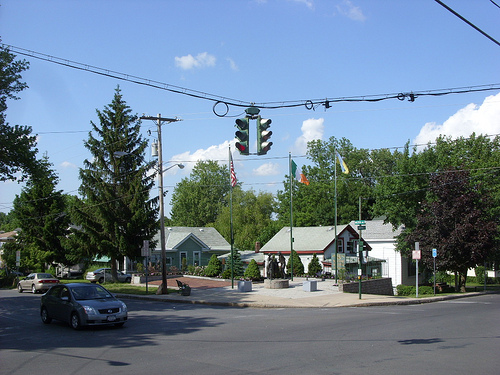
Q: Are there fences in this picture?
A: No, there are no fences.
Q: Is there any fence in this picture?
A: No, there are no fences.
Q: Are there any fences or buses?
A: No, there are no fences or buses.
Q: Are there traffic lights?
A: Yes, there is a traffic light.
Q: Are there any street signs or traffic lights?
A: Yes, there is a traffic light.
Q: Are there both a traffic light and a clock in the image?
A: No, there is a traffic light but no clocks.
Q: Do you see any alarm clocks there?
A: No, there are no alarm clocks.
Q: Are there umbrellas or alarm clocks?
A: No, there are no alarm clocks or umbrellas.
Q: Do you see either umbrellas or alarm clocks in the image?
A: No, there are no alarm clocks or umbrellas.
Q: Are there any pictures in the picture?
A: No, there are no pictures.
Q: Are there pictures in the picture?
A: No, there are no pictures.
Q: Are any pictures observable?
A: No, there are no pictures.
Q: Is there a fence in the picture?
A: No, there are no fences.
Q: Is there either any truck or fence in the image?
A: No, there are no fences or trucks.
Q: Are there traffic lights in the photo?
A: Yes, there is a traffic light.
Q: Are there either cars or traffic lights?
A: Yes, there is a traffic light.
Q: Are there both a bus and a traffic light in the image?
A: No, there is a traffic light but no buses.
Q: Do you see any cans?
A: No, there are no cans.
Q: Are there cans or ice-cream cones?
A: No, there are no cans or ice-cream cones.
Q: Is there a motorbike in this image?
A: No, there are no motorcycles.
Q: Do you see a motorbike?
A: No, there are no motorcycles.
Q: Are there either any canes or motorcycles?
A: No, there are no motorcycles or canes.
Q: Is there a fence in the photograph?
A: No, there are no fences.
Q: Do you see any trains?
A: No, there are no trains.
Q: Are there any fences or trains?
A: No, there are no trains or fences.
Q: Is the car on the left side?
A: Yes, the car is on the left of the image.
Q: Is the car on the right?
A: No, the car is on the left of the image.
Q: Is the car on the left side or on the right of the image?
A: The car is on the left of the image.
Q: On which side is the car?
A: The car is on the left of the image.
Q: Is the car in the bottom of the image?
A: Yes, the car is in the bottom of the image.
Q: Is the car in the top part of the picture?
A: No, the car is in the bottom of the image.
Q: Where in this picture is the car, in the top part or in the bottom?
A: The car is in the bottom of the image.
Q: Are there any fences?
A: No, there are no fences.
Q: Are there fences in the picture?
A: No, there are no fences.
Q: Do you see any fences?
A: No, there are no fences.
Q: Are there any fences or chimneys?
A: No, there are no fences or chimneys.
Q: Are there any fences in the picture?
A: No, there are no fences.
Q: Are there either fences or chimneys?
A: No, there are no fences or chimneys.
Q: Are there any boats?
A: No, there are no boats.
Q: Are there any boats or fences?
A: No, there are no boats or fences.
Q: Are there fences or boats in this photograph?
A: No, there are no boats or fences.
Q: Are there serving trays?
A: No, there are no serving trays.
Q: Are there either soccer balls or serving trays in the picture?
A: No, there are no serving trays or soccer balls.